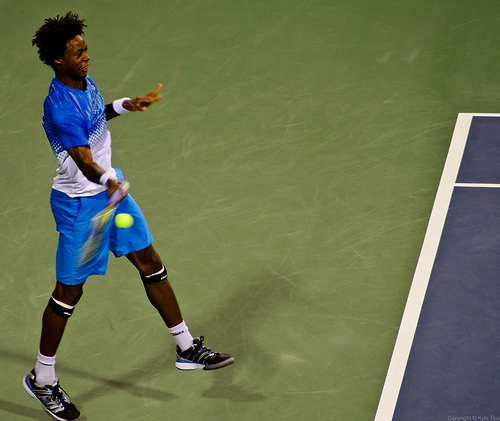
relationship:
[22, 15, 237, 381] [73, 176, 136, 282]
man holding racket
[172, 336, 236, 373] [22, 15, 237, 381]
shoe of a man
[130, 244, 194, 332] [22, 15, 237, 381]
leg of a man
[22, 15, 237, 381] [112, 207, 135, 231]
man hitting ball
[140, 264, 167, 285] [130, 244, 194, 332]
band across leg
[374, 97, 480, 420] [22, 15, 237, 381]
line near man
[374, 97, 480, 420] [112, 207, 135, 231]
line near ball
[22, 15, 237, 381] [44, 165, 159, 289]
man wearing shorts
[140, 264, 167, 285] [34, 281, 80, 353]
band on leg